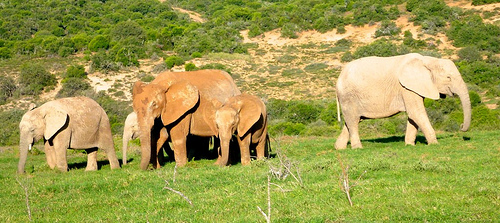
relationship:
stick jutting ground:
[248, 183, 285, 220] [80, 171, 449, 221]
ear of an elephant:
[37, 102, 60, 154] [10, 101, 112, 206]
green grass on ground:
[182, 174, 225, 204] [63, 167, 479, 210]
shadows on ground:
[69, 150, 275, 177] [18, 166, 497, 213]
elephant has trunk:
[334, 51, 473, 151] [456, 81, 472, 132]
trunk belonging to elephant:
[456, 83, 471, 133] [334, 51, 473, 151]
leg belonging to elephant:
[236, 131, 252, 166] [208, 91, 269, 169]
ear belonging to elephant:
[159, 79, 200, 125] [128, 65, 240, 173]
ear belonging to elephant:
[43, 107, 70, 140] [13, 92, 117, 174]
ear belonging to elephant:
[236, 98, 263, 138] [201, 90, 269, 168]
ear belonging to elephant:
[393, 55, 442, 101] [334, 51, 473, 151]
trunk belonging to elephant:
[16, 133, 31, 175] [13, 92, 117, 174]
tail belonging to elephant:
[334, 90, 342, 122] [334, 51, 473, 151]